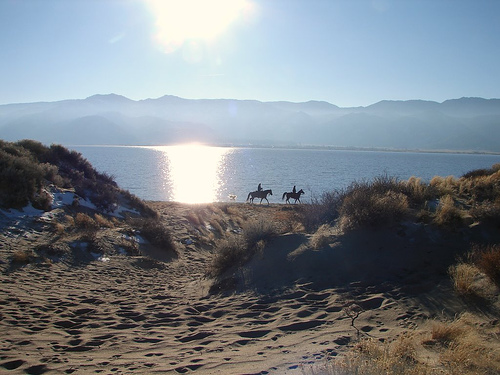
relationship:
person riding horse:
[291, 184, 297, 194] [279, 190, 306, 202]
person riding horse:
[254, 181, 264, 191] [241, 188, 272, 203]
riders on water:
[247, 183, 304, 203] [48, 142, 498, 207]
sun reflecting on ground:
[150, 2, 261, 47] [164, 200, 254, 296]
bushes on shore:
[1, 132, 146, 212] [17, 125, 497, 252]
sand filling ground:
[32, 260, 397, 373] [3, 195, 496, 373]